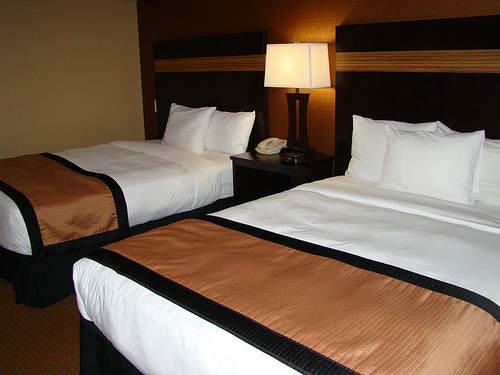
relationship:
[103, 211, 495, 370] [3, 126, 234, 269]
runner across bed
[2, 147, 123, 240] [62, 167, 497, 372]
runner across bed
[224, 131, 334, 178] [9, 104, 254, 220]
bedstand between bed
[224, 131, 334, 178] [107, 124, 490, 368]
bedstand between bed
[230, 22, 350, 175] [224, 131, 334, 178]
lamp on a bedstand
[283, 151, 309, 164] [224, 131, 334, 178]
alarm clock on a bedstand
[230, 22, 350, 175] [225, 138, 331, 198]
lamp on a night stand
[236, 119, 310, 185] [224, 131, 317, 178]
phone sitting on a bedstand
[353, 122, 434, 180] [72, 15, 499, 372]
pillow on bed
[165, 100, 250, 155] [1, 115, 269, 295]
pillows on bed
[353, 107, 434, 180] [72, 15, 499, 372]
pillow on bed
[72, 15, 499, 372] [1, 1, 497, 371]
bed in bedroom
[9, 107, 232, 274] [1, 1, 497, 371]
bed in bedroom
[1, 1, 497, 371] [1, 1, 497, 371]
bedroom at bedroom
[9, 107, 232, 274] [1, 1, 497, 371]
bed at bedroom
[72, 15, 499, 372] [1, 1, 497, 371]
bed at bedroom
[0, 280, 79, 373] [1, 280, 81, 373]
carpet on floor